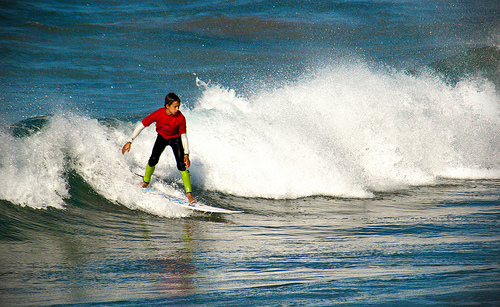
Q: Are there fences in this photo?
A: No, there are no fences.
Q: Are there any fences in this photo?
A: No, there are no fences.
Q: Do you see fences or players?
A: No, there are no fences or players.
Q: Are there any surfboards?
A: Yes, there is a surfboard.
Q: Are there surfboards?
A: Yes, there is a surfboard.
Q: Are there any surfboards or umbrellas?
A: Yes, there is a surfboard.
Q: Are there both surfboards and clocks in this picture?
A: No, there is a surfboard but no clocks.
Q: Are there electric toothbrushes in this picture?
A: No, there are no electric toothbrushes.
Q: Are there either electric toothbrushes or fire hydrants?
A: No, there are no electric toothbrushes or fire hydrants.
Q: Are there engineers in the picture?
A: No, there are no engineers.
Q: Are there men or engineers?
A: No, there are no engineers or men.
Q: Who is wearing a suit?
A: The boy is wearing a suit.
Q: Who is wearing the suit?
A: The boy is wearing a suit.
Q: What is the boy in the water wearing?
A: The boy is wearing a suit.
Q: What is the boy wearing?
A: The boy is wearing a suit.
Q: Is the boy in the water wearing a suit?
A: Yes, the boy is wearing a suit.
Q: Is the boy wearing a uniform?
A: No, the boy is wearing a suit.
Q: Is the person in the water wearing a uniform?
A: No, the boy is wearing a suit.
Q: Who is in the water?
A: The boy is in the water.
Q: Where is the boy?
A: The boy is in the water.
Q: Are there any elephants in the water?
A: No, there is a boy in the water.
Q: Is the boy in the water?
A: Yes, the boy is in the water.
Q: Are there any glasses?
A: No, there are no glasses.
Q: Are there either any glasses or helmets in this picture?
A: No, there are no glasses or helmets.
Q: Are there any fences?
A: No, there are no fences.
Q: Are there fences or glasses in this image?
A: No, there are no fences or glasses.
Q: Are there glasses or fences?
A: No, there are no fences or glasses.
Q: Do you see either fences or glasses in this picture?
A: No, there are no fences or glasses.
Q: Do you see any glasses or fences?
A: No, there are no fences or glasses.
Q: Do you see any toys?
A: No, there are no toys.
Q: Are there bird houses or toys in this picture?
A: No, there are no toys or bird houses.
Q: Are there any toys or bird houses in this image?
A: No, there are no toys or bird houses.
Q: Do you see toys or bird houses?
A: No, there are no toys or bird houses.